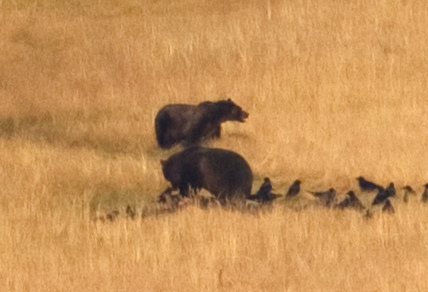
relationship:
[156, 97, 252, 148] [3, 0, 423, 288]
bear in field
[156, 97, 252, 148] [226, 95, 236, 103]
bear has ear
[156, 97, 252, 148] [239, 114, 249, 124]
bear has mouth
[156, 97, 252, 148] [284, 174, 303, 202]
bear near bird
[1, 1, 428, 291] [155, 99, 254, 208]
grass near bears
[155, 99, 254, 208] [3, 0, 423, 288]
bears in field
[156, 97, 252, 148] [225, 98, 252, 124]
bear has head